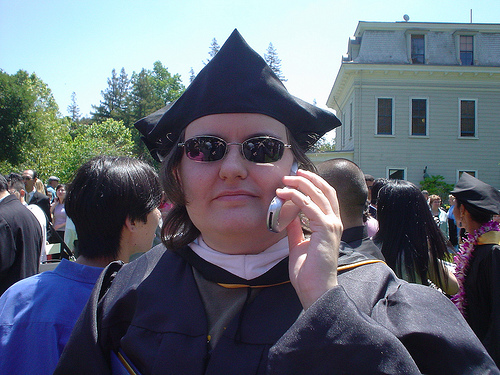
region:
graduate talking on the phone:
[50, 27, 495, 372]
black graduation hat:
[127, 28, 341, 143]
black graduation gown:
[52, 240, 489, 368]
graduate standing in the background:
[441, 176, 499, 343]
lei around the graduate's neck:
[447, 218, 492, 315]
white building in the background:
[322, 20, 499, 192]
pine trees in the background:
[0, 44, 273, 186]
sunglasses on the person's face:
[180, 134, 295, 159]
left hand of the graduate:
[280, 167, 339, 302]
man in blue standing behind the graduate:
[1, 152, 171, 371]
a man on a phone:
[134, 13, 345, 318]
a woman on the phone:
[141, 30, 341, 267]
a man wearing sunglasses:
[171, 113, 318, 243]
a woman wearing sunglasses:
[178, 108, 296, 233]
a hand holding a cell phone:
[262, 159, 349, 283]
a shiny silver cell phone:
[268, 153, 312, 240]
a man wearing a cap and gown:
[71, 31, 430, 373]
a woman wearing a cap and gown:
[109, 17, 406, 371]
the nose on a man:
[217, 157, 245, 182]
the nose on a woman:
[216, 160, 246, 180]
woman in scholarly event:
[77, 25, 479, 374]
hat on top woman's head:
[125, 16, 349, 131]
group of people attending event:
[0, 149, 65, 275]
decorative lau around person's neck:
[455, 225, 469, 317]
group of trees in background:
[2, 70, 128, 157]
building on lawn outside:
[328, 5, 497, 171]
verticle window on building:
[402, 95, 435, 144]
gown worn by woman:
[68, 246, 481, 373]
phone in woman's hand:
[262, 163, 304, 243]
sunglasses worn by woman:
[172, 131, 297, 166]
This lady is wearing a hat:
[113, 27, 371, 142]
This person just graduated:
[81, 51, 443, 367]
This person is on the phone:
[141, 67, 416, 334]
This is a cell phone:
[270, 190, 307, 234]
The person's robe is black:
[92, 233, 248, 338]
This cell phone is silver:
[270, 183, 302, 243]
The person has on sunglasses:
[175, 115, 324, 197]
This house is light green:
[326, 54, 496, 189]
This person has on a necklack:
[448, 226, 473, 299]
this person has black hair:
[53, 149, 147, 251]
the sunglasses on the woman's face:
[176, 133, 291, 163]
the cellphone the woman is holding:
[266, 157, 307, 232]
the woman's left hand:
[275, 168, 344, 294]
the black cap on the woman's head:
[133, 28, 343, 162]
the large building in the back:
[303, 6, 498, 189]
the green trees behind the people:
[0, 36, 336, 191]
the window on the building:
[375, 95, 395, 138]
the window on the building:
[408, 95, 429, 138]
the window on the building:
[456, 96, 479, 139]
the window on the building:
[410, 31, 426, 66]